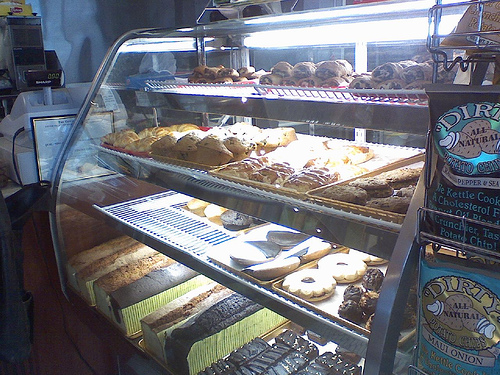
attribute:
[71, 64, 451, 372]
doughnuts — for sale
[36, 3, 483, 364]
case — glass, large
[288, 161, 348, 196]
doughnut — long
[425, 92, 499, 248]
bag — blue, gold, light blue, brown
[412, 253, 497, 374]
chips — maui onion, for sale, designed, light blue, gold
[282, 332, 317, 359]
brownies — for sale, chocolate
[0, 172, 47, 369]
stand — wood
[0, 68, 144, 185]
cash register — white, cash regiser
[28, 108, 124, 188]
paper — framed, black, gold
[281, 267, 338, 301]
cookies — for sale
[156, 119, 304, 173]
tray — muffins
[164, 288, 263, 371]
bread — for sale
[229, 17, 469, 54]
light — long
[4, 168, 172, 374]
floor — reddish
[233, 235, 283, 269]
donuts — glazed, chocolate dipped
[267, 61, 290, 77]
croisant — chocolate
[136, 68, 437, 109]
shelf — wire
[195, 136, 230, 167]
muffin — chocolate